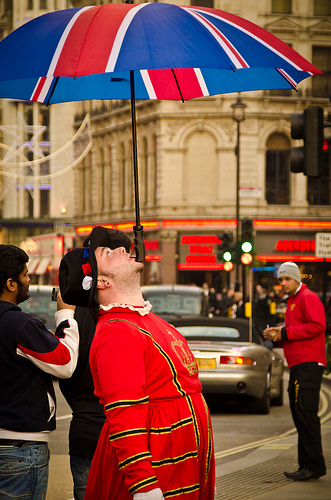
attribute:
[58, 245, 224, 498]
man — looking up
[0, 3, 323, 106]
umbrella — on chin, red, white, blue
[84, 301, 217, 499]
jacket — red, black, stripped, gold, white, dark blue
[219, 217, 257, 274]
traffic light — on corner, green, yellow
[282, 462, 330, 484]
boot — black, pointed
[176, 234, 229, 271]
sign — red, above store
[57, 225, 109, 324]
hat — black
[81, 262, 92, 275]
red object — on hat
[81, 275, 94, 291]
white object — on hat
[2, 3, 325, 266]
umbrella — white, red, blue, on chin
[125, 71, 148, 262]
handle — black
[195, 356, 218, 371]
license plate — yellow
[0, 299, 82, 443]
jacket — white, blue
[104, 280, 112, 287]
earring — in ear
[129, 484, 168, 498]
glove — white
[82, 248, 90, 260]
flower — on hat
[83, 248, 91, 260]
flower — blue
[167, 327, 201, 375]
crown — on chest, on costume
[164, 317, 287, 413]
convertible — on a street, sand-color, in traffic, silver, metallic color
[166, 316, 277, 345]
soft top — black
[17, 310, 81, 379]
sleeve — blue, red, white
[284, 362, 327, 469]
pants — black